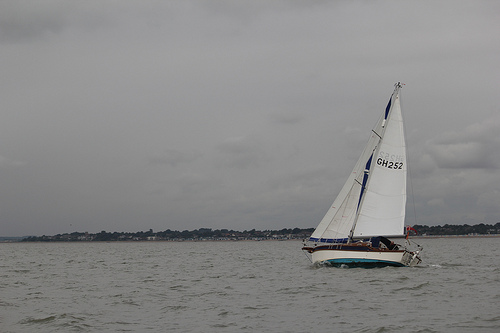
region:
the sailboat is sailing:
[290, 49, 431, 266]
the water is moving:
[112, 232, 350, 327]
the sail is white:
[308, 75, 413, 240]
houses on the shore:
[79, 225, 287, 245]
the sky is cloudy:
[242, 90, 495, 203]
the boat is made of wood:
[292, 235, 412, 266]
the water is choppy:
[240, 222, 498, 330]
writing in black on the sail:
[374, 152, 411, 179]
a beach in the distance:
[418, 224, 488, 241]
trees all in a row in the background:
[425, 214, 494, 236]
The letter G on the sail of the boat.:
[377, 155, 382, 167]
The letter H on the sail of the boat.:
[382, 156, 388, 168]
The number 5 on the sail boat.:
[394, 159, 397, 169]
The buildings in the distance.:
[43, 220, 498, 252]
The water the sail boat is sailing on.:
[4, 241, 498, 332]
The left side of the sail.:
[316, 105, 373, 240]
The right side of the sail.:
[372, 86, 407, 247]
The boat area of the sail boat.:
[299, 242, 410, 272]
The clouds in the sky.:
[115, 94, 497, 190]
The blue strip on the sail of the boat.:
[357, 75, 392, 239]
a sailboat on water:
[248, 38, 456, 310]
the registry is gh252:
[368, 146, 405, 181]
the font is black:
[362, 143, 444, 190]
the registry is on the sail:
[281, 63, 450, 299]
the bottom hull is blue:
[295, 34, 447, 267]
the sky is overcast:
[194, 28, 499, 303]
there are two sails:
[309, 44, 471, 319]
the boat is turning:
[299, 34, 491, 312]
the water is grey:
[149, 268, 293, 304]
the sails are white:
[266, 38, 471, 305]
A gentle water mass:
[4, 246, 293, 326]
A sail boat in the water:
[293, 71, 434, 279]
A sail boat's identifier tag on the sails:
[374, 156, 406, 175]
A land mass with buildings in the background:
[12, 226, 305, 244]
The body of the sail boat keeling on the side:
[301, 238, 426, 270]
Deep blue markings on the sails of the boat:
[308, 233, 349, 241]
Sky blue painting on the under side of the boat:
[325, 253, 391, 265]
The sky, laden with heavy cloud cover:
[4, 91, 311, 220]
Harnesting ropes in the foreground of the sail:
[322, 211, 352, 247]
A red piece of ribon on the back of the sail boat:
[398, 223, 420, 247]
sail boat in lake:
[302, 81, 421, 264]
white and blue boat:
[311, 245, 405, 269]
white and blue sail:
[311, 89, 408, 246]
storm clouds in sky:
[423, 121, 498, 181]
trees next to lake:
[28, 226, 498, 239]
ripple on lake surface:
[21, 313, 82, 329]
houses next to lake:
[41, 234, 313, 244]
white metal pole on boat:
[348, 77, 400, 242]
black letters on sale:
[378, 156, 405, 170]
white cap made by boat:
[422, 258, 461, 269]